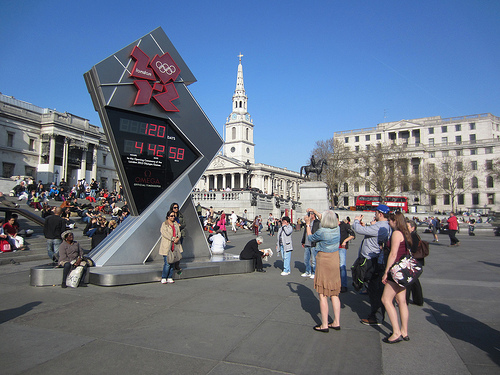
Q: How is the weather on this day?
A: It is clear.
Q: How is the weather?
A: It is clear.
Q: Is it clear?
A: Yes, it is clear.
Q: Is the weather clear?
A: Yes, it is clear.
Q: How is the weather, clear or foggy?
A: It is clear.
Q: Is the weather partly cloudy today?
A: No, it is clear.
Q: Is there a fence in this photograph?
A: No, there are no fences.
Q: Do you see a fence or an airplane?
A: No, there are no fences or airplanes.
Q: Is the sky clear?
A: Yes, the sky is clear.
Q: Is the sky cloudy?
A: No, the sky is clear.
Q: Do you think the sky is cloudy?
A: No, the sky is clear.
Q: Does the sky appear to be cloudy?
A: No, the sky is clear.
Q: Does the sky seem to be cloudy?
A: No, the sky is clear.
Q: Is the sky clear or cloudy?
A: The sky is clear.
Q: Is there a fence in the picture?
A: No, there are no fences.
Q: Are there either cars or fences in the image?
A: No, there are no fences or cars.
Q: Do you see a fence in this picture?
A: No, there are no fences.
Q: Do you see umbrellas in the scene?
A: No, there are no umbrellas.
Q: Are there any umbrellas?
A: No, there are no umbrellas.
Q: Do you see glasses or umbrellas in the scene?
A: No, there are no umbrellas or glasses.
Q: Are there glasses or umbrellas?
A: No, there are no umbrellas or glasses.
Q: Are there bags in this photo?
A: Yes, there is a bag.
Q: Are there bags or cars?
A: Yes, there is a bag.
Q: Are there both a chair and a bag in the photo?
A: No, there is a bag but no chairs.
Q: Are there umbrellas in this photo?
A: No, there are no umbrellas.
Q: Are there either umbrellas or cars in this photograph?
A: No, there are no umbrellas or cars.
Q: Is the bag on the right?
A: Yes, the bag is on the right of the image.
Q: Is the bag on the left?
A: No, the bag is on the right of the image.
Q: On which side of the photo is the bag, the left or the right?
A: The bag is on the right of the image.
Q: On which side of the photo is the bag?
A: The bag is on the right of the image.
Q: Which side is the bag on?
A: The bag is on the right of the image.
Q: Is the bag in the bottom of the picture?
A: Yes, the bag is in the bottom of the image.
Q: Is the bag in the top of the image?
A: No, the bag is in the bottom of the image.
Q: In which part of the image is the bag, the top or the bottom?
A: The bag is in the bottom of the image.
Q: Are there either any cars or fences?
A: No, there are no cars or fences.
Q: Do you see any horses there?
A: Yes, there is a horse.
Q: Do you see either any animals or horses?
A: Yes, there is a horse.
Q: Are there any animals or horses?
A: Yes, there is a horse.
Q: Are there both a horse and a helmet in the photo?
A: No, there is a horse but no helmets.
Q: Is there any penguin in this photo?
A: No, there are no penguins.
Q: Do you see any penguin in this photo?
A: No, there are no penguins.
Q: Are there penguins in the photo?
A: No, there are no penguins.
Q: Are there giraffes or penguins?
A: No, there are no penguins or giraffes.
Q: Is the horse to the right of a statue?
A: Yes, the horse is to the right of a statue.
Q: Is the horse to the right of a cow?
A: No, the horse is to the right of a statue.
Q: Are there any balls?
A: No, there are no balls.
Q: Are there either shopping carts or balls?
A: No, there are no balls or shopping carts.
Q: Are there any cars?
A: No, there are no cars.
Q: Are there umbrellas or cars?
A: No, there are no cars or umbrellas.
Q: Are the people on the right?
A: Yes, the people are on the right of the image.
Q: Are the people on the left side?
A: No, the people are on the right of the image.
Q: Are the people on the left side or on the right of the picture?
A: The people are on the right of the image.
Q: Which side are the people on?
A: The people are on the right of the image.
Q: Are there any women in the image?
A: Yes, there is a woman.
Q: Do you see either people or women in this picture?
A: Yes, there is a woman.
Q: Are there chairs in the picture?
A: No, there are no chairs.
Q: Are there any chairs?
A: No, there are no chairs.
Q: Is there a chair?
A: No, there are no chairs.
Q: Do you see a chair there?
A: No, there are no chairs.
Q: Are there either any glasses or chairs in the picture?
A: No, there are no chairs or glasses.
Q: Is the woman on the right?
A: Yes, the woman is on the right of the image.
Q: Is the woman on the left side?
A: No, the woman is on the right of the image.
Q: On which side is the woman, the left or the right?
A: The woman is on the right of the image.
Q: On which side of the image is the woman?
A: The woman is on the right of the image.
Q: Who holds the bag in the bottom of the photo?
A: The woman holds the bag.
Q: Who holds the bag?
A: The woman holds the bag.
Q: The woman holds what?
A: The woman holds the bag.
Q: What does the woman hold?
A: The woman holds the bag.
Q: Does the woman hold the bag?
A: Yes, the woman holds the bag.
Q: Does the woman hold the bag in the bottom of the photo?
A: Yes, the woman holds the bag.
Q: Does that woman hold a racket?
A: No, the woman holds the bag.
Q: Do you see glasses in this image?
A: No, there are no glasses.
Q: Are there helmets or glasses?
A: No, there are no glasses or helmets.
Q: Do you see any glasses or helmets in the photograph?
A: No, there are no glasses or helmets.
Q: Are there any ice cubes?
A: No, there are no ice cubes.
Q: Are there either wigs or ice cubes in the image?
A: No, there are no ice cubes or wigs.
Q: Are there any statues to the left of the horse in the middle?
A: Yes, there is a statue to the left of the horse.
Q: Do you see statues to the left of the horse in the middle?
A: Yes, there is a statue to the left of the horse.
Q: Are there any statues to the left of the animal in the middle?
A: Yes, there is a statue to the left of the horse.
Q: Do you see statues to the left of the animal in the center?
A: Yes, there is a statue to the left of the horse.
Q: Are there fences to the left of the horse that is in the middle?
A: No, there is a statue to the left of the horse.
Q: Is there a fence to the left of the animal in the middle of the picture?
A: No, there is a statue to the left of the horse.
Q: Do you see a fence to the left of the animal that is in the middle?
A: No, there is a statue to the left of the horse.